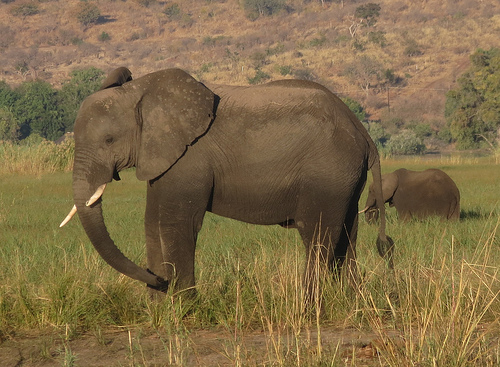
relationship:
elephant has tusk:
[56, 64, 396, 319] [85, 183, 107, 206]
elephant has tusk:
[56, 64, 396, 319] [53, 207, 76, 226]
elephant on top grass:
[56, 64, 396, 319] [3, 157, 498, 365]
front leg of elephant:
[153, 204, 207, 318] [21, 63, 418, 340]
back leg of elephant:
[298, 204, 340, 284] [25, 68, 403, 354]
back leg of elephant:
[330, 194, 376, 274] [25, 68, 403, 354]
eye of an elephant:
[94, 126, 124, 157] [36, 54, 403, 321]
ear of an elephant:
[110, 66, 234, 180] [32, 82, 376, 312]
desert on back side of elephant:
[23, 19, 461, 139] [56, 70, 412, 323]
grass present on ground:
[219, 250, 412, 327] [126, 279, 491, 362]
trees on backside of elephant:
[18, 70, 102, 138] [53, 77, 440, 338]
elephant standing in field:
[56, 64, 396, 319] [36, 177, 173, 262]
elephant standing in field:
[360, 152, 483, 237] [0, 156, 500, 367]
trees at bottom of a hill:
[18, 70, 102, 138] [0, 0, 500, 151]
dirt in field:
[156, 297, 351, 341] [33, 216, 487, 354]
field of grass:
[23, 114, 493, 352] [292, 232, 469, 362]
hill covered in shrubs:
[194, 19, 457, 164] [453, 88, 488, 136]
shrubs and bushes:
[453, 88, 488, 136] [338, 100, 449, 165]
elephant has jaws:
[36, 54, 403, 321] [66, 150, 136, 180]